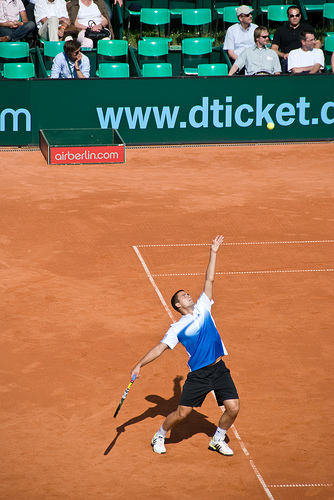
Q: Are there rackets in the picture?
A: Yes, there is a racket.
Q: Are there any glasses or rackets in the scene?
A: Yes, there is a racket.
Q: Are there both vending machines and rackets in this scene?
A: No, there is a racket but no vending machines.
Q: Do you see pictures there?
A: No, there are no pictures.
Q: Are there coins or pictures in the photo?
A: No, there are no pictures or coins.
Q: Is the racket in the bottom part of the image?
A: Yes, the racket is in the bottom of the image.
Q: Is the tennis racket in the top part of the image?
A: No, the tennis racket is in the bottom of the image.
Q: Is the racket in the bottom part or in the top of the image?
A: The racket is in the bottom of the image.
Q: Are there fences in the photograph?
A: No, there are no fences.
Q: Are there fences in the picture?
A: No, there are no fences.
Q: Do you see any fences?
A: No, there are no fences.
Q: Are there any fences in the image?
A: No, there are no fences.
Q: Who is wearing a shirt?
A: The man is wearing a shirt.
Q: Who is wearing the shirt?
A: The man is wearing a shirt.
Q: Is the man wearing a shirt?
A: Yes, the man is wearing a shirt.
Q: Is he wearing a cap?
A: No, the man is wearing a shirt.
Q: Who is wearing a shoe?
A: The man is wearing a shoe.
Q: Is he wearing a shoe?
A: Yes, the man is wearing a shoe.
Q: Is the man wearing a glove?
A: No, the man is wearing a shoe.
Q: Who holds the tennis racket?
A: The man holds the tennis racket.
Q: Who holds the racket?
A: The man holds the tennis racket.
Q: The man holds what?
A: The man holds the racket.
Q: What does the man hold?
A: The man holds the racket.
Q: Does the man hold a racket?
A: Yes, the man holds a racket.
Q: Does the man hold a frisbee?
A: No, the man holds a racket.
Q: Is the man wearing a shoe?
A: Yes, the man is wearing a shoe.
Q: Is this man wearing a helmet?
A: No, the man is wearing a shoe.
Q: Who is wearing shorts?
A: The man is wearing shorts.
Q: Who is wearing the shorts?
A: The man is wearing shorts.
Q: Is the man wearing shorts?
A: Yes, the man is wearing shorts.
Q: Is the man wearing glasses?
A: No, the man is wearing shorts.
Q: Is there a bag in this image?
A: Yes, there is a bag.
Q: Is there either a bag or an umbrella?
A: Yes, there is a bag.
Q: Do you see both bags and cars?
A: No, there is a bag but no cars.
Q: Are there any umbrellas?
A: No, there are no umbrellas.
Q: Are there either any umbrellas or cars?
A: No, there are no umbrellas or cars.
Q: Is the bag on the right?
A: No, the bag is on the left of the image.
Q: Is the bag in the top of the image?
A: Yes, the bag is in the top of the image.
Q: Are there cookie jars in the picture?
A: No, there are no cookie jars.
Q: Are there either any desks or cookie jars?
A: No, there are no cookie jars or desks.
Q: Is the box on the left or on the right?
A: The box is on the left of the image.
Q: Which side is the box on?
A: The box is on the left of the image.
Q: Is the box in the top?
A: Yes, the box is in the top of the image.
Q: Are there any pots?
A: No, there are no pots.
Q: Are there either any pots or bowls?
A: No, there are no pots or bowls.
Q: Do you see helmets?
A: No, there are no helmets.